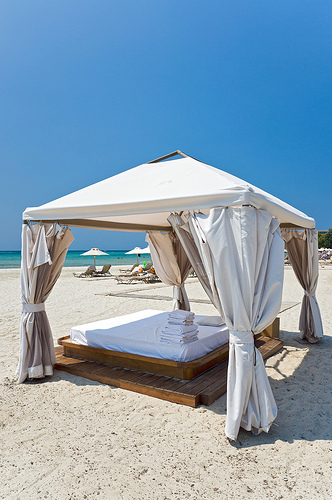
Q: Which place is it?
A: It is a beach.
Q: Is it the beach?
A: Yes, it is the beach.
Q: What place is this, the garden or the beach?
A: It is the beach.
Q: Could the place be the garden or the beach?
A: It is the beach.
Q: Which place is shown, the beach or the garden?
A: It is the beach.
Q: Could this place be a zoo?
A: No, it is a beach.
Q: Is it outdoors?
A: Yes, it is outdoors.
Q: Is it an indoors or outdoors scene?
A: It is outdoors.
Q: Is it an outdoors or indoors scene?
A: It is outdoors.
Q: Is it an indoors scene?
A: No, it is outdoors.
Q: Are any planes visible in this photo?
A: No, there are no planes.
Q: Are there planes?
A: No, there are no planes.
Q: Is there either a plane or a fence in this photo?
A: No, there are no airplanes or fences.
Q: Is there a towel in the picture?
A: Yes, there is a towel.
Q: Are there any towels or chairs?
A: Yes, there is a towel.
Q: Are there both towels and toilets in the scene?
A: No, there is a towel but no toilets.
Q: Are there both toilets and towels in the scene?
A: No, there is a towel but no toilets.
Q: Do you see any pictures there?
A: No, there are no pictures.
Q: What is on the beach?
A: The tent is on the beach.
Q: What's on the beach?
A: The tent is on the beach.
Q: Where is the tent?
A: The tent is on the beach.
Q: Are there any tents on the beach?
A: Yes, there is a tent on the beach.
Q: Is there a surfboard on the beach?
A: No, there is a tent on the beach.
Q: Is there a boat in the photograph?
A: No, there are no boats.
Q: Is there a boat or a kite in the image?
A: No, there are no boats or kites.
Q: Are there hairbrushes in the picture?
A: No, there are no hairbrushes.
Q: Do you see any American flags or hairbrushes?
A: No, there are no hairbrushes or American flags.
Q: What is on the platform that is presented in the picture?
A: The mattress is on the platform.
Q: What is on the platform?
A: The mattress is on the platform.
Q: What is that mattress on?
A: The mattress is on the platform.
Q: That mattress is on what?
A: The mattress is on the platform.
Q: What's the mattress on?
A: The mattress is on the platform.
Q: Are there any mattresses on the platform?
A: Yes, there is a mattress on the platform.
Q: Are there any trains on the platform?
A: No, there is a mattress on the platform.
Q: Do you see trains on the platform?
A: No, there is a mattress on the platform.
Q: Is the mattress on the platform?
A: Yes, the mattress is on the platform.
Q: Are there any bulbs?
A: No, there are no bulbs.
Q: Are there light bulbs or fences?
A: No, there are no light bulbs or fences.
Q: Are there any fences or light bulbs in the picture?
A: No, there are no light bulbs or fences.